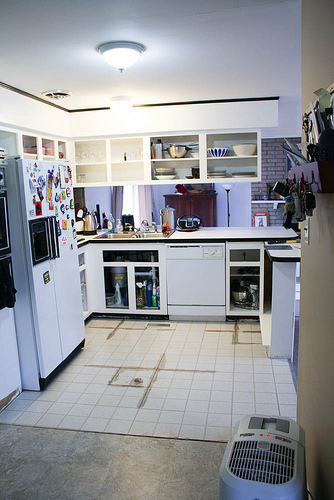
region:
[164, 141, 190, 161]
Silver bowl on shelf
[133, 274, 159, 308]
Cleaning products in cabinet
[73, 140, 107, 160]
Wine glasses on shelf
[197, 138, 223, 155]
Blue and white bowl on shelf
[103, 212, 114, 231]
Dish detergent near sink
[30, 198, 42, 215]
Red magnet on fridge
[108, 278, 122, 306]
White bottle in cabinet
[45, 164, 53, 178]
Blue clip on fridge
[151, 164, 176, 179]
Stack of plates on shelf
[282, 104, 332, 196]
Rack hanging on the wall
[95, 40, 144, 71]
A globe light on a ceiling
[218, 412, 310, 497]
A heater/air conditioning unit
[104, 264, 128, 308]
The drawerless cabinet that is white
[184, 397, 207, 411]
A single piece of tile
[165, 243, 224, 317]
A dishwasher hooked up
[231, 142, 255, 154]
A bowl in a cabinet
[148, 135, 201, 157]
A cabinet with small appliances in it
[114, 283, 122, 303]
A dish soap container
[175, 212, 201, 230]
A small appliance on a counter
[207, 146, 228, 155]
A blue and white bowl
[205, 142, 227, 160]
White bowl with blue design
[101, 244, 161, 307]
Cabinet with no doors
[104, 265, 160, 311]
Various cleaners under cabinet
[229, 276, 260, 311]
Mixer on cabinet shelf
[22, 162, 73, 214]
Magnets on refrigerator door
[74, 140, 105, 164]
Clear glassware in upper cabinet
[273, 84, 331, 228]
Mail holder with key hooks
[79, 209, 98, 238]
Stainless steel coffeepot on counter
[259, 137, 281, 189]
Brick wall of fireplace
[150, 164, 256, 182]
Stacks of dishes in cabinets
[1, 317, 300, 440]
a white tile floor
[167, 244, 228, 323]
a white dishwasher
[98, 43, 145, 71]
a small ceiling light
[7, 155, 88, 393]
a large white refrigerator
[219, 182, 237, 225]
part of a floor lamp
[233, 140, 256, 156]
a large white bowl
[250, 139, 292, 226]
part of a brick wall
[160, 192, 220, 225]
part of a brown cabinet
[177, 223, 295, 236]
a white counter top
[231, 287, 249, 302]
a large gray bowl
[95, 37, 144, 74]
A white domed ceiling light.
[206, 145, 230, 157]
A blue and white ceramic bowl.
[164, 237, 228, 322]
A white dishwasher.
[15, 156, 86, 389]
A white side by side refrigerator.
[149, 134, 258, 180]
Dishes in the kitchen cabinet.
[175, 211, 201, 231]
A small black radio.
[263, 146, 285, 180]
A white brick wall.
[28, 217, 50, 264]
The icemaker on a refrigerator.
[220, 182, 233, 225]
A black and white floor lamp.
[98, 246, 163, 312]
Cleaning supplies in a cabinet.